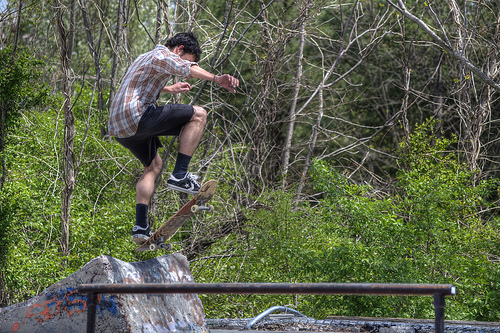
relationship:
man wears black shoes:
[108, 31, 239, 243] [123, 168, 207, 247]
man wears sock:
[108, 31, 239, 243] [118, 134, 219, 182]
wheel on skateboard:
[146, 241, 161, 254] [128, 174, 223, 259]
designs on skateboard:
[159, 218, 190, 234] [123, 179, 229, 251]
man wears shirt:
[108, 31, 239, 243] [86, 29, 174, 119]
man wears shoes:
[108, 31, 239, 243] [132, 142, 198, 235]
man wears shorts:
[108, 31, 239, 243] [115, 106, 199, 156]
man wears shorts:
[108, 31, 239, 243] [117, 101, 191, 163]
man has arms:
[108, 31, 239, 243] [190, 67, 288, 109]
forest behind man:
[1, 1, 498, 318] [108, 31, 239, 243]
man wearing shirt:
[108, 31, 239, 243] [102, 44, 194, 139]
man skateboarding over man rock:
[108, 31, 239, 243] [1, 254, 202, 333]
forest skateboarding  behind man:
[1, 5, 451, 279] [108, 31, 239, 243]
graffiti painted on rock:
[3, 292, 132, 327] [0, 235, 210, 330]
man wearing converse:
[111, 15, 250, 235] [157, 163, 216, 197]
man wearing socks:
[108, 31, 239, 243] [130, 193, 151, 230]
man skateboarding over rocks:
[108, 31, 239, 243] [0, 252, 210, 330]